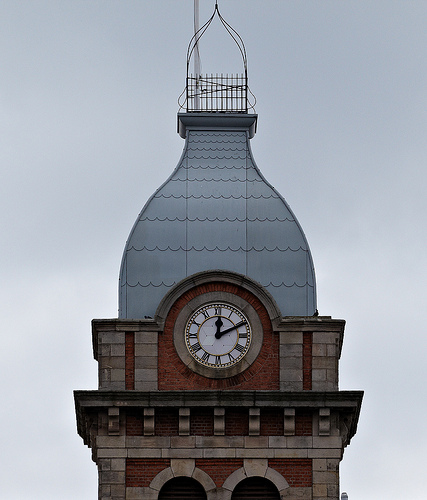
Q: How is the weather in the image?
A: It is cloudy.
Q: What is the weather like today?
A: It is cloudy.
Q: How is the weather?
A: It is cloudy.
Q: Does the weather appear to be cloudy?
A: Yes, it is cloudy.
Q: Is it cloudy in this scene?
A: Yes, it is cloudy.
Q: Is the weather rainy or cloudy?
A: It is cloudy.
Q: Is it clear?
A: No, it is cloudy.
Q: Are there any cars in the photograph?
A: No, there are no cars.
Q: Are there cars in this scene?
A: No, there are no cars.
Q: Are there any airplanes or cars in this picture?
A: No, there are no cars or airplanes.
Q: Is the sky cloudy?
A: Yes, the sky is cloudy.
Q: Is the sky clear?
A: No, the sky is cloudy.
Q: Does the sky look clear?
A: No, the sky is cloudy.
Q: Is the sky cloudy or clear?
A: The sky is cloudy.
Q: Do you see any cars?
A: No, there are no cars.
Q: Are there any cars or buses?
A: No, there are no cars or buses.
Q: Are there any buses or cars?
A: No, there are no cars or buses.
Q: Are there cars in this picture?
A: No, there are no cars.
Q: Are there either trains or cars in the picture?
A: No, there are no cars or trains.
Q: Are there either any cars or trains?
A: No, there are no cars or trains.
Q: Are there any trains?
A: No, there are no trains.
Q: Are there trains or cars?
A: No, there are no trains or cars.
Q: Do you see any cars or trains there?
A: No, there are no trains or cars.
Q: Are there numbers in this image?
A: Yes, there are numbers.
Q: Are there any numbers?
A: Yes, there are numbers.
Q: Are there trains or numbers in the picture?
A: Yes, there are numbers.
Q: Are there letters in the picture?
A: No, there are no letters.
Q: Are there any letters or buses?
A: No, there are no letters or buses.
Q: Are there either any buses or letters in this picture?
A: No, there are no letters or buses.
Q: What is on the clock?
A: The numbers are on the clock.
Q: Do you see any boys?
A: No, there are no boys.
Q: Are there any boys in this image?
A: No, there are no boys.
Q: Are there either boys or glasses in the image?
A: No, there are no boys or glasses.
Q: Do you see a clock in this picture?
A: Yes, there is a clock.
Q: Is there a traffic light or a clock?
A: Yes, there is a clock.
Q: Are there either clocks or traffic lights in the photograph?
A: Yes, there is a clock.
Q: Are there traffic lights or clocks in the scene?
A: Yes, there is a clock.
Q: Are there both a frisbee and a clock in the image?
A: No, there is a clock but no frisbees.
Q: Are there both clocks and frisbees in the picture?
A: No, there is a clock but no frisbees.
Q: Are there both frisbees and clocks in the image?
A: No, there is a clock but no frisbees.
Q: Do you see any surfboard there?
A: No, there are no surfboards.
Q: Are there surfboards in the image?
A: No, there are no surfboards.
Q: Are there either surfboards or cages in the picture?
A: No, there are no surfboards or cages.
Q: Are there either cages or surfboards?
A: No, there are no surfboards or cages.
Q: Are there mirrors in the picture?
A: No, there are no mirrors.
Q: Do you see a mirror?
A: No, there are no mirrors.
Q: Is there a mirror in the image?
A: No, there are no mirrors.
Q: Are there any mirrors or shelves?
A: No, there are no mirrors or shelves.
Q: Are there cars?
A: No, there are no cars.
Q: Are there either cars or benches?
A: No, there are no cars or benches.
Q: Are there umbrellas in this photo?
A: No, there are no umbrellas.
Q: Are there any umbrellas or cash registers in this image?
A: No, there are no umbrellas or cash registers.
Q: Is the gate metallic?
A: Yes, the gate is metallic.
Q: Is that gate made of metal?
A: Yes, the gate is made of metal.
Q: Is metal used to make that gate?
A: Yes, the gate is made of metal.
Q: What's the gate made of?
A: The gate is made of metal.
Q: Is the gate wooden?
A: No, the gate is metallic.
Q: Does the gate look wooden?
A: No, the gate is metallic.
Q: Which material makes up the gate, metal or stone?
A: The gate is made of metal.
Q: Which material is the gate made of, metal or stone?
A: The gate is made of metal.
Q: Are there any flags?
A: No, there are no flags.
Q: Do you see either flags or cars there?
A: No, there are no flags or cars.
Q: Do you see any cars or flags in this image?
A: No, there are no flags or cars.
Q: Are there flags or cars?
A: No, there are no flags or cars.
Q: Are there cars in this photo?
A: No, there are no cars.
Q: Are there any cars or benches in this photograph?
A: No, there are no cars or benches.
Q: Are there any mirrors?
A: No, there are no mirrors.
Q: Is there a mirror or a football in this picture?
A: No, there are no mirrors or footballs.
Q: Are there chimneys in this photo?
A: No, there are no chimneys.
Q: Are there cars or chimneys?
A: No, there are no chimneys or cars.